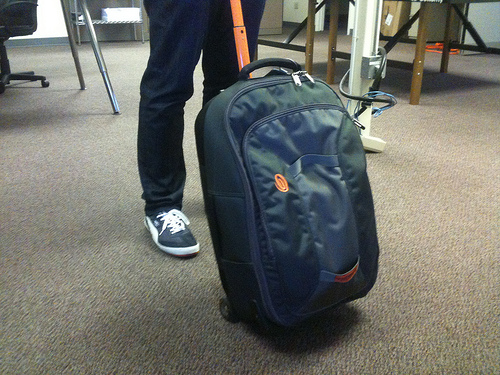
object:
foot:
[144, 207, 200, 257]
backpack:
[194, 54, 384, 334]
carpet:
[0, 37, 500, 375]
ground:
[0, 35, 500, 375]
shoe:
[140, 206, 201, 258]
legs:
[410, 3, 435, 109]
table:
[301, 0, 494, 103]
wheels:
[217, 300, 234, 320]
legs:
[77, 0, 124, 116]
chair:
[0, 0, 51, 91]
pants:
[141, 1, 266, 221]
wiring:
[351, 47, 388, 119]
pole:
[348, 0, 381, 140]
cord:
[427, 39, 463, 60]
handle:
[228, 0, 254, 78]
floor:
[0, 37, 499, 375]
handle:
[239, 54, 309, 81]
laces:
[159, 208, 195, 234]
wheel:
[41, 82, 51, 90]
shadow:
[219, 295, 365, 359]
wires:
[339, 68, 402, 113]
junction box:
[359, 55, 388, 80]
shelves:
[77, 9, 145, 40]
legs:
[129, 1, 204, 224]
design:
[273, 173, 291, 195]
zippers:
[290, 70, 305, 91]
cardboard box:
[381, 0, 407, 38]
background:
[0, 0, 500, 375]